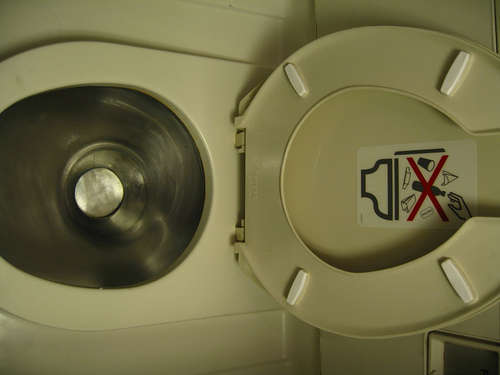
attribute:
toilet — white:
[4, 4, 490, 357]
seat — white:
[4, 40, 233, 323]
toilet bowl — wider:
[57, 153, 167, 227]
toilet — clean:
[2, 18, 494, 335]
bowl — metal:
[0, 49, 252, 333]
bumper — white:
[281, 60, 308, 100]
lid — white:
[237, 16, 499, 344]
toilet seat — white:
[0, 22, 499, 333]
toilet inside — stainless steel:
[0, 89, 208, 286]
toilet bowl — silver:
[0, 84, 210, 291]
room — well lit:
[1, 0, 499, 373]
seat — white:
[1, 17, 498, 352]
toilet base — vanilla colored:
[1, 23, 263, 326]